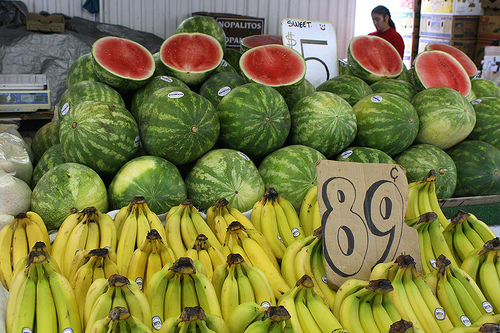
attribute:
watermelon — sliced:
[87, 30, 159, 91]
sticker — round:
[21, 325, 35, 331]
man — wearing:
[355, 4, 416, 59]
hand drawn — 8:
[320, 175, 369, 277]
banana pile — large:
[1, 164, 498, 331]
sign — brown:
[319, 155, 424, 292]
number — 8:
[321, 175, 368, 280]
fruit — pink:
[237, 37, 310, 89]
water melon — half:
[54, 99, 147, 177]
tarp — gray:
[18, 21, 106, 109]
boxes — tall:
[391, 0, 498, 85]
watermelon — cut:
[412, 47, 470, 98]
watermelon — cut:
[344, 30, 400, 77]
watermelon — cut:
[238, 43, 309, 88]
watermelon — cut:
[158, 31, 226, 81]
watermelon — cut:
[89, 33, 169, 87]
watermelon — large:
[215, 81, 291, 156]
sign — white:
[279, 18, 335, 80]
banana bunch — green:
[2, 242, 86, 332]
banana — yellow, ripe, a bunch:
[158, 197, 320, 324]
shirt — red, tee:
[356, 28, 443, 55]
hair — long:
[375, 6, 400, 26]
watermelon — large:
[135, 86, 221, 164]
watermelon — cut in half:
[88, 36, 156, 91]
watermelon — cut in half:
[159, 30, 223, 86]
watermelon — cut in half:
[235, 41, 308, 95]